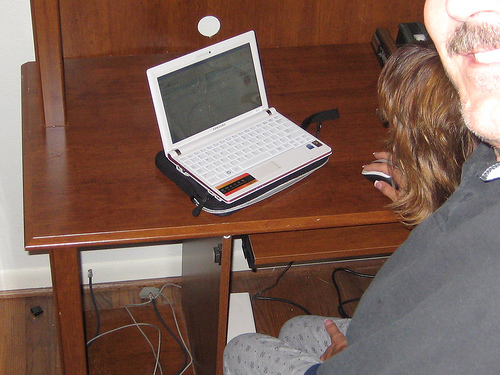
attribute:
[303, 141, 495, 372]
sweater — grey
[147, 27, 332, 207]
laptop — white, open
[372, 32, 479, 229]
hair — brown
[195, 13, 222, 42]
white circle — white 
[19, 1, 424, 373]
desk — wooden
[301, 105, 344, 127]
strap — black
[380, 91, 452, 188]
hair — brown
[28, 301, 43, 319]
piece — black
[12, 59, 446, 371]
desk — brown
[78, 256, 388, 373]
cords — black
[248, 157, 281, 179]
mouse pad — white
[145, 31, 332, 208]
computer — on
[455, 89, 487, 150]
hair — grey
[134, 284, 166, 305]
wire — grey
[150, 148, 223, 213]
cover — black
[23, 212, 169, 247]
desk. — back 